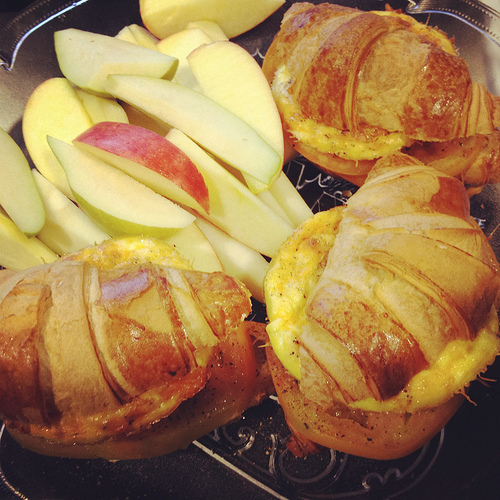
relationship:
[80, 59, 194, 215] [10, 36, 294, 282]
skin on apples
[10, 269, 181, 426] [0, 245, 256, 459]
bacon on croissant sandwich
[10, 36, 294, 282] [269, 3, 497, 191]
apples and croissant sandwich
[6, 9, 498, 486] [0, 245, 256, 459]
platter has croissant sandwich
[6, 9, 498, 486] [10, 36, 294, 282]
platter has apples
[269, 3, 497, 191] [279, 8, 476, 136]
croissant sandwich has top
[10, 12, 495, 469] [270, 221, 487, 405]
sandwiches have eggs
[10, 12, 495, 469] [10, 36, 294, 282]
sandwiches by apples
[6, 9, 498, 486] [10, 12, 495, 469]
platter has sandwiches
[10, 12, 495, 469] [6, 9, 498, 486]
sandwiches on platter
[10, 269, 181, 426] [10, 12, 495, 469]
bacon on sandwiches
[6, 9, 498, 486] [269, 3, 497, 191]
platter holds croissant sandwich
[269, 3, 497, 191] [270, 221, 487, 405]
croissant sandwich has eggs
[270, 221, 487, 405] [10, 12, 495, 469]
eggs on sandwiches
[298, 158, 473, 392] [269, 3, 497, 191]
bread for croissant sandwich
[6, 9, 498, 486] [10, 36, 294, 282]
platter holds apples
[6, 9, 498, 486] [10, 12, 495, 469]
platter holds sandwiches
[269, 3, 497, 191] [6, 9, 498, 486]
croissant sandwich on platter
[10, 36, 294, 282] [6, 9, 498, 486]
apples on platter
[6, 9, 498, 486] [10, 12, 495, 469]
platter under sandwiches